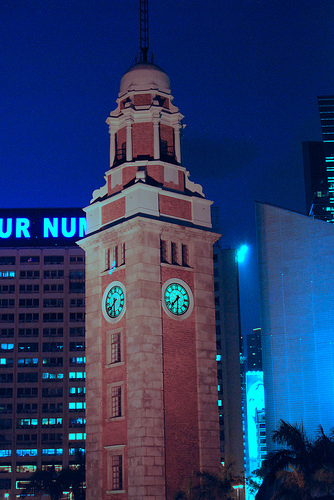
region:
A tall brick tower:
[83, 6, 217, 494]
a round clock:
[156, 277, 197, 324]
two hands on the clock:
[171, 295, 183, 308]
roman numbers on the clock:
[179, 294, 187, 311]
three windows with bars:
[102, 330, 124, 492]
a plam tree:
[258, 432, 333, 489]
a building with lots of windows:
[12, 268, 82, 443]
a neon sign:
[1, 209, 79, 243]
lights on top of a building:
[236, 240, 251, 265]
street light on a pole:
[232, 484, 245, 496]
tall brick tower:
[74, 51, 220, 499]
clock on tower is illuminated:
[164, 282, 188, 313]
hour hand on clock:
[176, 295, 179, 313]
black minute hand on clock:
[169, 295, 179, 306]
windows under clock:
[109, 330, 121, 362]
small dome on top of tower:
[116, 61, 172, 92]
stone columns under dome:
[152, 116, 163, 157]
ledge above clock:
[74, 213, 221, 250]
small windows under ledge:
[159, 240, 167, 263]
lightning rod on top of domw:
[138, 1, 154, 61]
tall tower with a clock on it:
[61, 4, 236, 497]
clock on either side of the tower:
[91, 280, 197, 331]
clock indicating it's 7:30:
[158, 278, 197, 321]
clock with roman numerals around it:
[92, 274, 140, 325]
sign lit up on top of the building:
[0, 210, 101, 245]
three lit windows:
[41, 416, 66, 425]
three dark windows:
[15, 384, 41, 398]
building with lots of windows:
[2, 207, 105, 498]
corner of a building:
[231, 253, 255, 498]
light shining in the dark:
[232, 235, 251, 271]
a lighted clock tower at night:
[73, 37, 232, 496]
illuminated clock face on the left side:
[95, 269, 128, 328]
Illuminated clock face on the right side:
[157, 272, 194, 322]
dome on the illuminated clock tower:
[102, 58, 182, 122]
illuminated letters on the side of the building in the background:
[0, 213, 86, 237]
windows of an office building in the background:
[0, 251, 84, 458]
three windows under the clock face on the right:
[102, 327, 125, 498]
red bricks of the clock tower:
[162, 322, 199, 491]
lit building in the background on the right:
[250, 186, 331, 431]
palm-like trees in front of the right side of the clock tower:
[246, 413, 332, 498]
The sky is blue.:
[1, 0, 333, 370]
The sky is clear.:
[0, 0, 333, 366]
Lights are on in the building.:
[2, 269, 85, 456]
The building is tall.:
[1, 208, 244, 498]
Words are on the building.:
[0, 207, 89, 244]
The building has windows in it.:
[1, 247, 94, 498]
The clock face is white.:
[161, 279, 193, 317]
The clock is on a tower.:
[73, 3, 224, 498]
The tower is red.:
[73, 1, 223, 498]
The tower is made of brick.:
[75, 0, 224, 497]